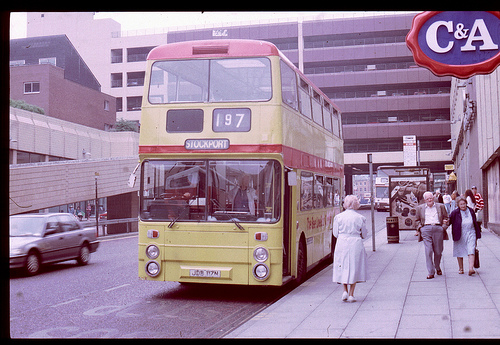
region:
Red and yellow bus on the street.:
[128, 27, 327, 302]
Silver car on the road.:
[9, 200, 109, 280]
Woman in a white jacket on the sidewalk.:
[318, 181, 388, 308]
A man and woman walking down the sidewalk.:
[410, 171, 488, 286]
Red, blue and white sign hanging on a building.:
[392, 9, 498, 84]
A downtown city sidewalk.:
[288, 295, 490, 330]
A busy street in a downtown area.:
[8, 194, 245, 331]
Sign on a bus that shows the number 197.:
[206, 98, 254, 134]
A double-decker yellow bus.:
[119, 27, 334, 307]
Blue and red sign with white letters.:
[405, 8, 499, 95]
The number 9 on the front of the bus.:
[220, 113, 235, 127]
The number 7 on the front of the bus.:
[231, 112, 243, 129]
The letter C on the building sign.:
[423, 20, 456, 60]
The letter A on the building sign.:
[465, 18, 493, 52]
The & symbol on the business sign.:
[454, 14, 467, 39]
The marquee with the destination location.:
[183, 137, 230, 149]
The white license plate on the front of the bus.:
[186, 265, 224, 278]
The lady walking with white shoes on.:
[322, 185, 369, 304]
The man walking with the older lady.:
[405, 189, 452, 279]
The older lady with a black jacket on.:
[447, 195, 482, 276]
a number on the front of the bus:
[209, 106, 255, 133]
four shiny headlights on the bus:
[144, 241, 277, 293]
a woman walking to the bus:
[337, 188, 377, 306]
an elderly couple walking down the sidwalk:
[417, 189, 494, 270]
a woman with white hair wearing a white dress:
[310, 184, 368, 307]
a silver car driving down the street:
[9, 201, 105, 273]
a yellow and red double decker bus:
[126, 45, 300, 292]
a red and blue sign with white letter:
[407, 5, 498, 73]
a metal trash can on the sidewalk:
[379, 217, 405, 244]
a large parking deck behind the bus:
[336, 23, 425, 130]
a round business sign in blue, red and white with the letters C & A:
[409, 12, 499, 82]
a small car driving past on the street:
[11, 208, 108, 285]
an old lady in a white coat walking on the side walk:
[328, 189, 371, 301]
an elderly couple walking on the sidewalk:
[411, 192, 488, 278]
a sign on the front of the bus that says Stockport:
[183, 136, 235, 155]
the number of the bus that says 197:
[207, 105, 259, 132]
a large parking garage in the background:
[299, 22, 438, 162]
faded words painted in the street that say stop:
[71, 292, 233, 343]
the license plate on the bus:
[186, 263, 228, 283]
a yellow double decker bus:
[146, 35, 320, 302]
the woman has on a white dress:
[326, 207, 368, 286]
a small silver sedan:
[8, 195, 108, 282]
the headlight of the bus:
[243, 245, 285, 287]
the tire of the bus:
[291, 237, 328, 299]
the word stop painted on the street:
[83, 287, 240, 336]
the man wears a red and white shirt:
[463, 180, 493, 215]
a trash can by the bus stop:
[381, 212, 411, 249]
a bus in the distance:
[376, 157, 423, 219]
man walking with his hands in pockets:
[398, 192, 458, 276]